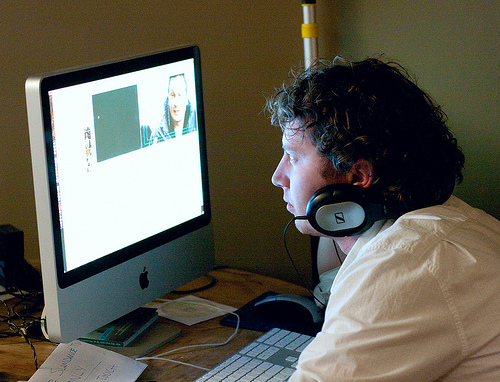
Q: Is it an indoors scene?
A: Yes, it is indoors.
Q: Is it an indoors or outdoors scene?
A: It is indoors.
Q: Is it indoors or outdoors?
A: It is indoors.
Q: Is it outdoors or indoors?
A: It is indoors.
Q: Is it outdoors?
A: No, it is indoors.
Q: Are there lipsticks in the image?
A: No, there are no lipsticks.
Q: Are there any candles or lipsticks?
A: No, there are no lipsticks or candles.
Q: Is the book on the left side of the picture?
A: Yes, the book is on the left of the image.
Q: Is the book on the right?
A: No, the book is on the left of the image.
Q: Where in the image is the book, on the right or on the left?
A: The book is on the left of the image.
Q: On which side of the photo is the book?
A: The book is on the left of the image.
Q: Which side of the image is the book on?
A: The book is on the left of the image.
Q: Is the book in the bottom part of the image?
A: Yes, the book is in the bottom of the image.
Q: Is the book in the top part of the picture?
A: No, the book is in the bottom of the image.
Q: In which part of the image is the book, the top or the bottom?
A: The book is in the bottom of the image.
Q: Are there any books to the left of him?
A: Yes, there is a book to the left of the man.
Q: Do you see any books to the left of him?
A: Yes, there is a book to the left of the man.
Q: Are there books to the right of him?
A: No, the book is to the left of the man.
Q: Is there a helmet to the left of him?
A: No, there is a book to the left of the man.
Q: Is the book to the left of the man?
A: Yes, the book is to the left of the man.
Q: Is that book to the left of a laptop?
A: No, the book is to the left of the man.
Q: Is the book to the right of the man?
A: No, the book is to the left of the man.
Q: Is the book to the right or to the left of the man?
A: The book is to the left of the man.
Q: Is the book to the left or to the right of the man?
A: The book is to the left of the man.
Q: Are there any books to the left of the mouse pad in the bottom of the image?
A: Yes, there is a book to the left of the mousepad.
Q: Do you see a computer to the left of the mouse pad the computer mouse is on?
A: No, there is a book to the left of the mousepad.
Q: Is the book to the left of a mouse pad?
A: Yes, the book is to the left of a mouse pad.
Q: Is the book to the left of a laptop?
A: No, the book is to the left of a mouse pad.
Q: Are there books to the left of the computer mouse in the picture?
A: Yes, there is a book to the left of the computer mouse.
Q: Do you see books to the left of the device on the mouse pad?
A: Yes, there is a book to the left of the computer mouse.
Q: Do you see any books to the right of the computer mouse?
A: No, the book is to the left of the computer mouse.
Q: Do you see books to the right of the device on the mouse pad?
A: No, the book is to the left of the computer mouse.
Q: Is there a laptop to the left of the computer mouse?
A: No, there is a book to the left of the computer mouse.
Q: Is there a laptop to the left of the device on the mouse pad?
A: No, there is a book to the left of the computer mouse.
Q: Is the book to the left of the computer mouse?
A: Yes, the book is to the left of the computer mouse.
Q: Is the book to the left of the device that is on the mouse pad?
A: Yes, the book is to the left of the computer mouse.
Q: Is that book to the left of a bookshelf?
A: No, the book is to the left of the computer mouse.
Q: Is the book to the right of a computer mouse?
A: No, the book is to the left of a computer mouse.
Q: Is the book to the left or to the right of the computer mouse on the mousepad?
A: The book is to the left of the mouse.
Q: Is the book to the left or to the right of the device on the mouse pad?
A: The book is to the left of the mouse.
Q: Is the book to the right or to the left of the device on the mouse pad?
A: The book is to the left of the mouse.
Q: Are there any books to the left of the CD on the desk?
A: Yes, there is a book to the left of the CD.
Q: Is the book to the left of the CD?
A: Yes, the book is to the left of the CD.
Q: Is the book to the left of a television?
A: No, the book is to the left of the CD.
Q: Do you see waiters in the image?
A: No, there are no waiters.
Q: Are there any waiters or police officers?
A: No, there are no waiters or police officers.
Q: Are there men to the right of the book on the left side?
A: Yes, there is a man to the right of the book.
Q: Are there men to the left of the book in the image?
A: No, the man is to the right of the book.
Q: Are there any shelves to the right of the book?
A: No, there is a man to the right of the book.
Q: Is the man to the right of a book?
A: Yes, the man is to the right of a book.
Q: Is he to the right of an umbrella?
A: No, the man is to the right of a book.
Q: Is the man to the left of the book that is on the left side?
A: No, the man is to the right of the book.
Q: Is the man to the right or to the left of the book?
A: The man is to the right of the book.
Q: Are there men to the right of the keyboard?
A: Yes, there is a man to the right of the keyboard.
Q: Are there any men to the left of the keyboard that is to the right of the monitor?
A: No, the man is to the right of the keyboard.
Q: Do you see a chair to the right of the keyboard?
A: No, there is a man to the right of the keyboard.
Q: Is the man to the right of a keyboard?
A: Yes, the man is to the right of a keyboard.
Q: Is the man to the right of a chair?
A: No, the man is to the right of a keyboard.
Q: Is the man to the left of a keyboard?
A: No, the man is to the right of a keyboard.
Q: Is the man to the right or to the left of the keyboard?
A: The man is to the right of the keyboard.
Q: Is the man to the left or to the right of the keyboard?
A: The man is to the right of the keyboard.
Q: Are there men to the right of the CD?
A: Yes, there is a man to the right of the CD.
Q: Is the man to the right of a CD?
A: Yes, the man is to the right of a CD.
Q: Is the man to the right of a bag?
A: No, the man is to the right of a CD.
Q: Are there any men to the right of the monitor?
A: Yes, there is a man to the right of the monitor.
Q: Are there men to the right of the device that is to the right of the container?
A: Yes, there is a man to the right of the monitor.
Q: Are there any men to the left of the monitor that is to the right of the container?
A: No, the man is to the right of the monitor.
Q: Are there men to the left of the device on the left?
A: No, the man is to the right of the monitor.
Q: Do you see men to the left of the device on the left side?
A: No, the man is to the right of the monitor.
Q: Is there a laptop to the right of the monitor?
A: No, there is a man to the right of the monitor.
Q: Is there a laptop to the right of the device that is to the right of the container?
A: No, there is a man to the right of the monitor.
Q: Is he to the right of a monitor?
A: Yes, the man is to the right of a monitor.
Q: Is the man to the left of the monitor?
A: No, the man is to the right of the monitor.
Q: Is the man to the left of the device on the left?
A: No, the man is to the right of the monitor.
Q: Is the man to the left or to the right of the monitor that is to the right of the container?
A: The man is to the right of the monitor.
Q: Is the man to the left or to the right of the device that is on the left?
A: The man is to the right of the monitor.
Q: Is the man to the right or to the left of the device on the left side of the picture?
A: The man is to the right of the monitor.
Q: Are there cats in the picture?
A: No, there are no cats.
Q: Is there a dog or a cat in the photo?
A: No, there are no cats or dogs.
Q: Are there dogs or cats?
A: No, there are no cats or dogs.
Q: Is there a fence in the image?
A: No, there are no fences.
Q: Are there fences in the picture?
A: No, there are no fences.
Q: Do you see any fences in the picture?
A: No, there are no fences.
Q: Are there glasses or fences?
A: No, there are no fences or glasses.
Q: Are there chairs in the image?
A: No, there are no chairs.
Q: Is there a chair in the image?
A: No, there are no chairs.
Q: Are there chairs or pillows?
A: No, there are no chairs or pillows.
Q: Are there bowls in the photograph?
A: No, there are no bowls.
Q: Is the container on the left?
A: Yes, the container is on the left of the image.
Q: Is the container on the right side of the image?
A: No, the container is on the left of the image.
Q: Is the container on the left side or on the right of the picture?
A: The container is on the left of the image.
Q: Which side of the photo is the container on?
A: The container is on the left of the image.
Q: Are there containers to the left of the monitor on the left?
A: Yes, there is a container to the left of the monitor.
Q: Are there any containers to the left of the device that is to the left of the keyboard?
A: Yes, there is a container to the left of the monitor.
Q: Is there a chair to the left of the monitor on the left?
A: No, there is a container to the left of the monitor.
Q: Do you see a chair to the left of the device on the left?
A: No, there is a container to the left of the monitor.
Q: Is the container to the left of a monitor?
A: Yes, the container is to the left of a monitor.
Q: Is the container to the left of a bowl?
A: No, the container is to the left of a monitor.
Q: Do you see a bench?
A: No, there are no benches.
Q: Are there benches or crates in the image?
A: No, there are no benches or crates.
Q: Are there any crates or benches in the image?
A: No, there are no benches or crates.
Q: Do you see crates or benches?
A: No, there are no benches or crates.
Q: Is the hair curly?
A: Yes, the hair is curly.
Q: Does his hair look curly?
A: Yes, the hair is curly.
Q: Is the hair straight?
A: No, the hair is curly.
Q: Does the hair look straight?
A: No, the hair is curly.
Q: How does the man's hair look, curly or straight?
A: The hair is curly.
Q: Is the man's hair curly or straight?
A: The hair is curly.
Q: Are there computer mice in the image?
A: Yes, there is a computer mouse.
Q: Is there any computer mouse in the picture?
A: Yes, there is a computer mouse.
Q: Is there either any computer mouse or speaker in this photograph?
A: Yes, there is a computer mouse.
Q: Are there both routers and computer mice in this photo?
A: No, there is a computer mouse but no routers.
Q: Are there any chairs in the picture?
A: No, there are no chairs.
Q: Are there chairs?
A: No, there are no chairs.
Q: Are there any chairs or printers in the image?
A: No, there are no chairs or printers.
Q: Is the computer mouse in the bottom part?
A: Yes, the computer mouse is in the bottom of the image.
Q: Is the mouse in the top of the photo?
A: No, the mouse is in the bottom of the image.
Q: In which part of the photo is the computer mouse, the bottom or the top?
A: The computer mouse is in the bottom of the image.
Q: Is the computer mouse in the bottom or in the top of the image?
A: The computer mouse is in the bottom of the image.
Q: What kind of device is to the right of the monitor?
A: The device is a computer mouse.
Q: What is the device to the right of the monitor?
A: The device is a computer mouse.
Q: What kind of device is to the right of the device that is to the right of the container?
A: The device is a computer mouse.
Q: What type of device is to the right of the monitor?
A: The device is a computer mouse.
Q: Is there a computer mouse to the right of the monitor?
A: Yes, there is a computer mouse to the right of the monitor.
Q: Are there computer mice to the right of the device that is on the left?
A: Yes, there is a computer mouse to the right of the monitor.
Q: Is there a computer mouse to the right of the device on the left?
A: Yes, there is a computer mouse to the right of the monitor.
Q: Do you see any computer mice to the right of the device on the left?
A: Yes, there is a computer mouse to the right of the monitor.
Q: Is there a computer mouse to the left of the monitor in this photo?
A: No, the computer mouse is to the right of the monitor.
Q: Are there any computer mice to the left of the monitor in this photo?
A: No, the computer mouse is to the right of the monitor.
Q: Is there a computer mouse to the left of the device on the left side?
A: No, the computer mouse is to the right of the monitor.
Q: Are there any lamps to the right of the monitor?
A: No, there is a computer mouse to the right of the monitor.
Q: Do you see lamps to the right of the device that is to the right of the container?
A: No, there is a computer mouse to the right of the monitor.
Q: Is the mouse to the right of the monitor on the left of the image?
A: Yes, the mouse is to the right of the monitor.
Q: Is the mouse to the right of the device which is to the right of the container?
A: Yes, the mouse is to the right of the monitor.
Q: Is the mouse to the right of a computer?
A: No, the mouse is to the right of the monitor.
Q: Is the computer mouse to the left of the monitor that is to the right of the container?
A: No, the computer mouse is to the right of the monitor.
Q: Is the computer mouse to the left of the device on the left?
A: No, the computer mouse is to the right of the monitor.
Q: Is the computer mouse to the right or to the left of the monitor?
A: The computer mouse is to the right of the monitor.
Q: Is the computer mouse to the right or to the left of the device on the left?
A: The computer mouse is to the right of the monitor.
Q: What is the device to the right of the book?
A: The device is a computer mouse.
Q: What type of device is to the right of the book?
A: The device is a computer mouse.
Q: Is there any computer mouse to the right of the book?
A: Yes, there is a computer mouse to the right of the book.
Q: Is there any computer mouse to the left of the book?
A: No, the computer mouse is to the right of the book.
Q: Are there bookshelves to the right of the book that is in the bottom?
A: No, there is a computer mouse to the right of the book.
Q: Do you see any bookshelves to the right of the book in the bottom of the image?
A: No, there is a computer mouse to the right of the book.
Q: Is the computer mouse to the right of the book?
A: Yes, the computer mouse is to the right of the book.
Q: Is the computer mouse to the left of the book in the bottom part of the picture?
A: No, the computer mouse is to the right of the book.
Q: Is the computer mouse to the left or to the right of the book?
A: The computer mouse is to the right of the book.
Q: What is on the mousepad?
A: The computer mouse is on the mousepad.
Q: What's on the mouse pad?
A: The computer mouse is on the mousepad.